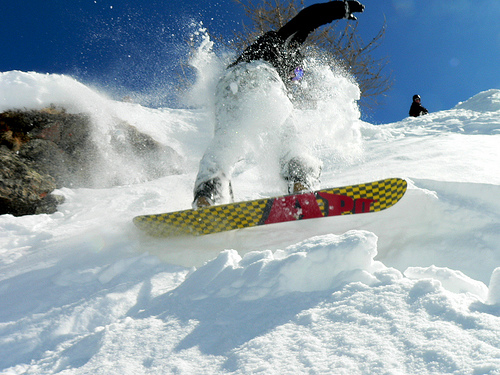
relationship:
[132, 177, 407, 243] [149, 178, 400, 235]
board has pattern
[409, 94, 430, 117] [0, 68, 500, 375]
man on hill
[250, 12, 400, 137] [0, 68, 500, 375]
tree on hill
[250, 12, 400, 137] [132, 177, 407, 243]
tree above board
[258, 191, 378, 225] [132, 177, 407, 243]
letters on board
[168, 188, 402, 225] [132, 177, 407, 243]
underside on board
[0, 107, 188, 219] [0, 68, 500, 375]
rock on hill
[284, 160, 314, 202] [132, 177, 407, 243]
boot on board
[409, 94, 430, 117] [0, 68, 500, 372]
man on top a hill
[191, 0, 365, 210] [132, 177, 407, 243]
man on a board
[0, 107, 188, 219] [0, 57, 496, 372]
rock sticking out of snow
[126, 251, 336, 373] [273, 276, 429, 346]
shadow on snow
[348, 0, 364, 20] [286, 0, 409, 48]
glove on hand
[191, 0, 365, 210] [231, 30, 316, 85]
man wearing coat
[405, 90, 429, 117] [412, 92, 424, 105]
man has a head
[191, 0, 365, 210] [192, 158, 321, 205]
man wearing boots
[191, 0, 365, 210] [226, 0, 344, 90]
man wearing coat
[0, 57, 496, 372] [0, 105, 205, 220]
snow on rock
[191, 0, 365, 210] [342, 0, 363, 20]
man wearing gloves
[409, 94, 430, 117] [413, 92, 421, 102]
man wearing helmet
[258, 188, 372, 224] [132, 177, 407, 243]
letters on board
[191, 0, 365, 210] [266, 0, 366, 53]
man has arm